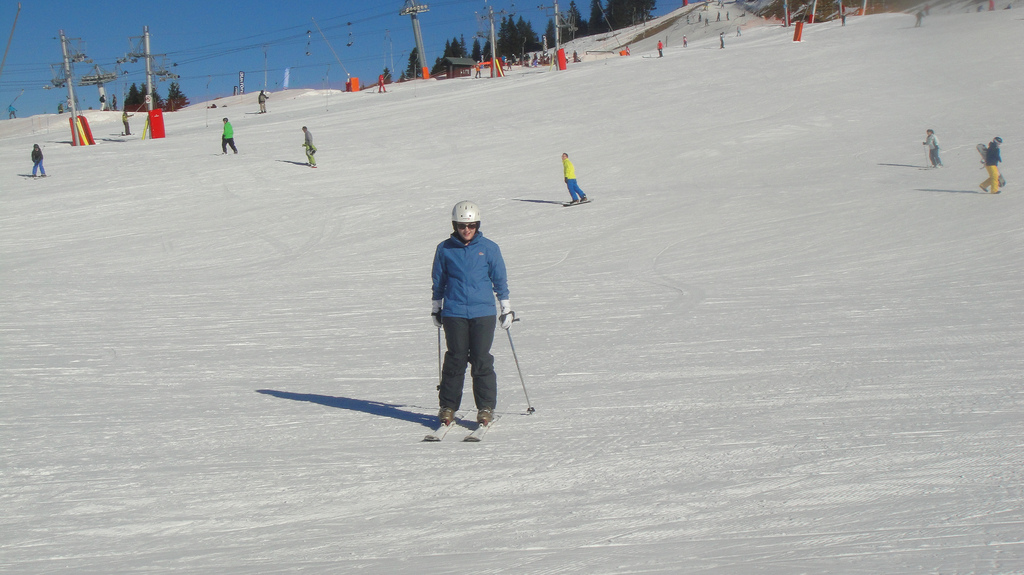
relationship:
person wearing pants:
[977, 136, 1006, 194] [982, 161, 1003, 199]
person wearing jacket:
[561, 152, 592, 206] [562, 161, 578, 181]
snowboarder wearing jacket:
[218, 113, 238, 155] [219, 122, 233, 143]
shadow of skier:
[257, 385, 479, 436] [426, 201, 537, 445]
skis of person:
[426, 414, 499, 447] [429, 205, 519, 433]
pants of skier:
[980, 165, 1000, 193] [917, 129, 943, 165]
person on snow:
[29, 142, 48, 182] [3, 1, 1021, 570]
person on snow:
[117, 101, 130, 137] [3, 1, 1021, 570]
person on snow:
[218, 114, 238, 154] [3, 1, 1021, 570]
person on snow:
[976, 134, 1006, 196] [3, 1, 1021, 570]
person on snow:
[426, 200, 512, 426] [3, 1, 1021, 570]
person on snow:
[215, 113, 244, 156] [3, 1, 1021, 570]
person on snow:
[293, 120, 320, 169] [3, 1, 1021, 570]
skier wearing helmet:
[426, 201, 537, 445] [446, 201, 482, 231]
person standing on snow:
[431, 200, 514, 426] [3, 1, 1021, 570]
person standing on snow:
[293, 125, 319, 167] [128, 222, 385, 350]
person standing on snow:
[554, 146, 589, 205] [3, 1, 1021, 570]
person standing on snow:
[915, 120, 953, 172] [832, 197, 968, 319]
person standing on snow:
[377, 70, 391, 94] [3, 1, 1021, 570]